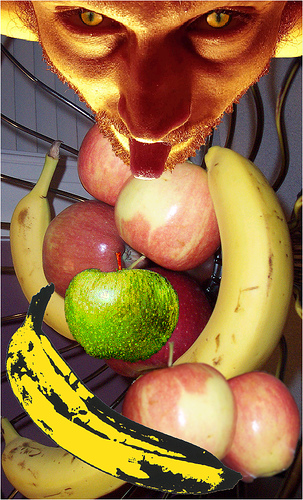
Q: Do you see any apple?
A: Yes, there is an apple.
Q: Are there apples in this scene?
A: Yes, there is an apple.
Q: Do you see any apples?
A: Yes, there is an apple.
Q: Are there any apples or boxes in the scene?
A: Yes, there is an apple.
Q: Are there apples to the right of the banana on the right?
A: No, the apple is to the left of the banana.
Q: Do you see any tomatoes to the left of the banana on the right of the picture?
A: No, there is an apple to the left of the banana.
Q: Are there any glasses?
A: No, there are no glasses.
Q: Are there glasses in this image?
A: No, there are no glasses.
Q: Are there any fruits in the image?
A: Yes, there is a fruit.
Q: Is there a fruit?
A: Yes, there is a fruit.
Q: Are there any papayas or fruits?
A: Yes, there is a fruit.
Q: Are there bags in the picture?
A: No, there are no bags.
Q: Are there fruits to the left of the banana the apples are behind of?
A: Yes, there is a fruit to the left of the banana.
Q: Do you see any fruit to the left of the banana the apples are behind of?
A: Yes, there is a fruit to the left of the banana.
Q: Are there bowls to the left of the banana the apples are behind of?
A: No, there is a fruit to the left of the banana.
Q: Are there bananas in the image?
A: Yes, there is a banana.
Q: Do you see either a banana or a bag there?
A: Yes, there is a banana.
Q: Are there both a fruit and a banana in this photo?
A: Yes, there are both a banana and a fruit.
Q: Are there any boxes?
A: No, there are no boxes.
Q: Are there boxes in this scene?
A: No, there are no boxes.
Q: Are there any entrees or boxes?
A: No, there are no boxes or entrees.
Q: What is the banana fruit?
A: The fruit is a banana.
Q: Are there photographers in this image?
A: No, there are no photographers.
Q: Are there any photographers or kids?
A: No, there are no photographers or kids.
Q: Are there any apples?
A: Yes, there are apples.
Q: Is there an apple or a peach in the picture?
A: Yes, there are apples.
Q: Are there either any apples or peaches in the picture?
A: Yes, there are apples.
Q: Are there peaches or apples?
A: Yes, there are apples.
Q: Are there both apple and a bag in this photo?
A: No, there are apples but no bags.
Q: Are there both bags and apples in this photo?
A: No, there are apples but no bags.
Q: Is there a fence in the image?
A: No, there are no fences.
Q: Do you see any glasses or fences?
A: No, there are no fences or glasses.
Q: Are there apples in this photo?
A: Yes, there are apples.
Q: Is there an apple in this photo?
A: Yes, there are apples.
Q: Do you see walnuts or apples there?
A: Yes, there are apples.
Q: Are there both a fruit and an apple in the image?
A: Yes, there are both an apple and a fruit.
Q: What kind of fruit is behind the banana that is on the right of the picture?
A: The fruits are apples.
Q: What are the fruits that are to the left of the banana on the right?
A: The fruits are apples.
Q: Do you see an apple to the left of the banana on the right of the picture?
A: Yes, there are apples to the left of the banana.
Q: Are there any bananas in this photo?
A: Yes, there is a banana.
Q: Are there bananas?
A: Yes, there is a banana.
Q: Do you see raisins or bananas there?
A: Yes, there is a banana.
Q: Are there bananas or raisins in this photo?
A: Yes, there is a banana.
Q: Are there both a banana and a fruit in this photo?
A: Yes, there are both a banana and a fruit.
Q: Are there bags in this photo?
A: No, there are no bags.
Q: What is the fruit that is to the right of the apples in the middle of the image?
A: The fruit is a banana.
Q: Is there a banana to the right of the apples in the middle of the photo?
A: Yes, there is a banana to the right of the apples.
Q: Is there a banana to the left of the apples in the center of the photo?
A: No, the banana is to the right of the apples.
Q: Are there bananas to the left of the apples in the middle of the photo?
A: No, the banana is to the right of the apples.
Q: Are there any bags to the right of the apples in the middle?
A: No, there is a banana to the right of the apples.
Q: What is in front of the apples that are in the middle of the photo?
A: The banana is in front of the apples.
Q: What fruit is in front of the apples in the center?
A: The fruit is a banana.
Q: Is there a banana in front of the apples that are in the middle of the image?
A: Yes, there is a banana in front of the apples.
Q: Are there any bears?
A: No, there are no bears.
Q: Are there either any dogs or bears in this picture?
A: No, there are no bears or dogs.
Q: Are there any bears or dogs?
A: No, there are no bears or dogs.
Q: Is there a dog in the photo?
A: No, there are no dogs.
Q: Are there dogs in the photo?
A: No, there are no dogs.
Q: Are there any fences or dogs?
A: No, there are no dogs or fences.